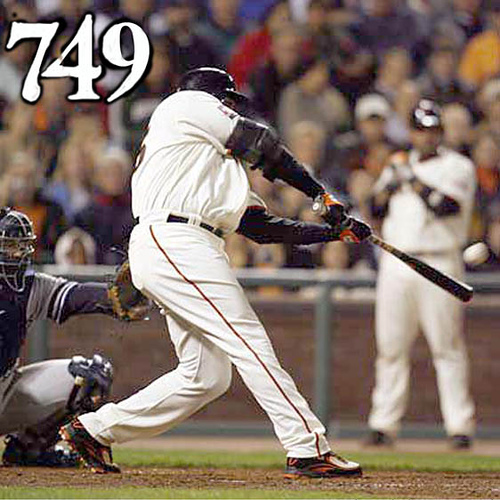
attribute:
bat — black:
[311, 198, 475, 302]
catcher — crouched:
[0, 206, 153, 466]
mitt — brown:
[107, 256, 156, 321]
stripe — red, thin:
[148, 224, 323, 458]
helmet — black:
[172, 66, 251, 102]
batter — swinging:
[58, 67, 372, 479]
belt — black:
[133, 216, 223, 239]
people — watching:
[0, 0, 499, 302]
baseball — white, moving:
[462, 241, 489, 267]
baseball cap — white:
[355, 93, 391, 122]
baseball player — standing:
[365, 97, 478, 449]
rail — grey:
[24, 263, 499, 438]